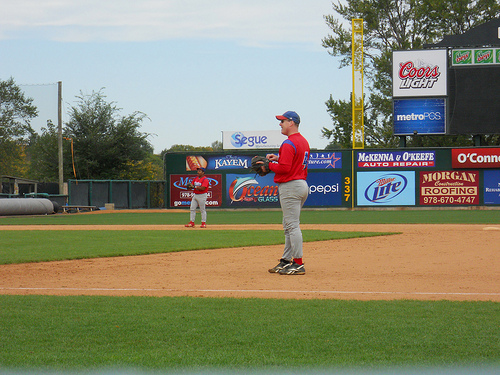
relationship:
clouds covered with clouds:
[3, 4, 330, 38] [3, 4, 330, 38]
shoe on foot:
[181, 220, 198, 230] [184, 217, 196, 232]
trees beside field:
[67, 101, 154, 172] [5, 204, 497, 371]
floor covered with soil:
[4, 210, 499, 370] [412, 235, 459, 287]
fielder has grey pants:
[256, 105, 313, 281] [267, 177, 318, 272]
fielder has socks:
[264, 111, 308, 277] [290, 243, 302, 270]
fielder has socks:
[264, 111, 308, 277] [275, 250, 292, 265]